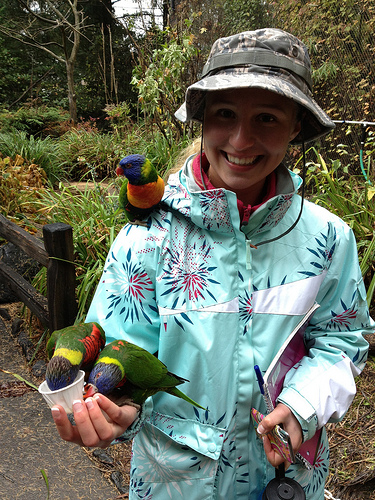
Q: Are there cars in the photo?
A: No, there are no cars.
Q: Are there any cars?
A: No, there are no cars.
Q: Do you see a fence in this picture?
A: Yes, there is a fence.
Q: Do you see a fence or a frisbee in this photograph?
A: Yes, there is a fence.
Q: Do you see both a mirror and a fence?
A: No, there is a fence but no mirrors.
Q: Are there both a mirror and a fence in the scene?
A: No, there is a fence but no mirrors.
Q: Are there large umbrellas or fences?
A: Yes, there is a large fence.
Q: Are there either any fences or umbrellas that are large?
A: Yes, the fence is large.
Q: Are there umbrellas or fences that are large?
A: Yes, the fence is large.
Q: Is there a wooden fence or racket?
A: Yes, there is a wood fence.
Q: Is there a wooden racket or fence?
A: Yes, there is a wood fence.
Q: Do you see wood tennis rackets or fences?
A: Yes, there is a wood fence.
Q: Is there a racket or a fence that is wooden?
A: Yes, the fence is wooden.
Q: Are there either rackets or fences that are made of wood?
A: Yes, the fence is made of wood.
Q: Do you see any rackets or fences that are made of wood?
A: Yes, the fence is made of wood.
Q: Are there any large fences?
A: Yes, there is a large fence.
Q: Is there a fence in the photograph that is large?
A: Yes, there is a fence that is large.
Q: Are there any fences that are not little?
A: Yes, there is a large fence.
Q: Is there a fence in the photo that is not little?
A: Yes, there is a large fence.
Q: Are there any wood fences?
A: Yes, there is a wood fence.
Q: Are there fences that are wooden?
A: Yes, there is a fence that is wooden.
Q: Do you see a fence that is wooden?
A: Yes, there is a fence that is wooden.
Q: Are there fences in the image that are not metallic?
A: Yes, there is a wooden fence.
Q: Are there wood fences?
A: Yes, there is a fence that is made of wood.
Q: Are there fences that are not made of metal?
A: Yes, there is a fence that is made of wood.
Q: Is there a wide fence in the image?
A: Yes, there is a wide fence.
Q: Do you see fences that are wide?
A: Yes, there is a fence that is wide.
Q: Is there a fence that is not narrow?
A: Yes, there is a wide fence.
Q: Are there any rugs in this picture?
A: No, there are no rugs.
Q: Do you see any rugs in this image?
A: No, there are no rugs.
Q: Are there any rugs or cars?
A: No, there are no rugs or cars.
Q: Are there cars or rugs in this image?
A: No, there are no rugs or cars.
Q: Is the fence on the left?
A: Yes, the fence is on the left of the image.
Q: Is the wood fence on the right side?
A: No, the fence is on the left of the image.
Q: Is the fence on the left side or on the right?
A: The fence is on the left of the image.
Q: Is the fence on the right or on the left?
A: The fence is on the left of the image.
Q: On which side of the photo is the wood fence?
A: The fence is on the left of the image.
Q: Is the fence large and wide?
A: Yes, the fence is large and wide.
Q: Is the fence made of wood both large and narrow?
A: No, the fence is large but wide.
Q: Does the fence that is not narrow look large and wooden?
A: Yes, the fence is large and wooden.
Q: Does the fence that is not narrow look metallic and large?
A: No, the fence is large but wooden.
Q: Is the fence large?
A: Yes, the fence is large.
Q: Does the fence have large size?
A: Yes, the fence is large.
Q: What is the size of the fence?
A: The fence is large.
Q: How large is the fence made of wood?
A: The fence is large.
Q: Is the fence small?
A: No, the fence is large.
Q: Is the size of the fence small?
A: No, the fence is large.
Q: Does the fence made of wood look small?
A: No, the fence is large.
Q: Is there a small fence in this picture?
A: No, there is a fence but it is large.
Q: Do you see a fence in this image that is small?
A: No, there is a fence but it is large.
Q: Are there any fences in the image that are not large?
A: No, there is a fence but it is large.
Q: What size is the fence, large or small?
A: The fence is large.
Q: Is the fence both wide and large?
A: Yes, the fence is wide and large.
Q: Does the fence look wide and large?
A: Yes, the fence is wide and large.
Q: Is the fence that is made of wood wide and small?
A: No, the fence is wide but large.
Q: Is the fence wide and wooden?
A: Yes, the fence is wide and wooden.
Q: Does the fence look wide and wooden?
A: Yes, the fence is wide and wooden.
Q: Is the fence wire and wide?
A: No, the fence is wide but wooden.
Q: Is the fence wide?
A: Yes, the fence is wide.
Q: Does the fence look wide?
A: Yes, the fence is wide.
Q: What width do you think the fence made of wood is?
A: The fence is wide.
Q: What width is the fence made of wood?
A: The fence is wide.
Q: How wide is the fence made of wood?
A: The fence is wide.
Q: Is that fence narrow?
A: No, the fence is wide.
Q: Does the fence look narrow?
A: No, the fence is wide.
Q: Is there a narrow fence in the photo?
A: No, there is a fence but it is wide.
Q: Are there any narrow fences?
A: No, there is a fence but it is wide.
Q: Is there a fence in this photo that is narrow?
A: No, there is a fence but it is wide.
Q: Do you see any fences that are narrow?
A: No, there is a fence but it is wide.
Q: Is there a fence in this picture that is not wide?
A: No, there is a fence but it is wide.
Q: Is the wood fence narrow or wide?
A: The fence is wide.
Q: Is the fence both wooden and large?
A: Yes, the fence is wooden and large.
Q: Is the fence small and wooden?
A: No, the fence is wooden but large.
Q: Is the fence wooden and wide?
A: Yes, the fence is wooden and wide.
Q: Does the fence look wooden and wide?
A: Yes, the fence is wooden and wide.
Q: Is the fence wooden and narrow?
A: No, the fence is wooden but wide.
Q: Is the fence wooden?
A: Yes, the fence is wooden.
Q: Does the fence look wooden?
A: Yes, the fence is wooden.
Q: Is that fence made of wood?
A: Yes, the fence is made of wood.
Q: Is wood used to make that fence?
A: Yes, the fence is made of wood.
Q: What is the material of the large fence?
A: The fence is made of wood.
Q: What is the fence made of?
A: The fence is made of wood.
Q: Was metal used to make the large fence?
A: No, the fence is made of wood.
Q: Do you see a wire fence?
A: No, there is a fence but it is made of wood.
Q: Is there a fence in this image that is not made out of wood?
A: No, there is a fence but it is made of wood.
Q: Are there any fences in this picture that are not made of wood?
A: No, there is a fence but it is made of wood.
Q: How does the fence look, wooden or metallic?
A: The fence is wooden.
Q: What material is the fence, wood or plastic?
A: The fence is made of wood.